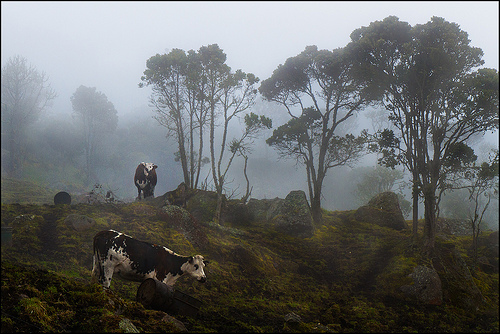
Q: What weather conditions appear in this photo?
A: It is foggy.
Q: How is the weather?
A: It is foggy.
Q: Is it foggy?
A: Yes, it is foggy.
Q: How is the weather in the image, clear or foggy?
A: It is foggy.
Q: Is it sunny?
A: No, it is foggy.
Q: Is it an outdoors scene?
A: Yes, it is outdoors.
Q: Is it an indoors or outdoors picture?
A: It is outdoors.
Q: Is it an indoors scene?
A: No, it is outdoors.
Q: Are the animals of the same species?
A: Yes, all the animals are cows.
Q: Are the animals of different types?
A: No, all the animals are cows.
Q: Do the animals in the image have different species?
A: No, all the animals are cows.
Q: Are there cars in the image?
A: No, there are no cars.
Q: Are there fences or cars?
A: No, there are no cars or fences.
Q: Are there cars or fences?
A: No, there are no cars or fences.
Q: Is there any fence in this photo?
A: No, there are no fences.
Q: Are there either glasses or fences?
A: No, there are no fences or glasses.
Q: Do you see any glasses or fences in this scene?
A: No, there are no fences or glasses.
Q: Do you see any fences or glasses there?
A: No, there are no fences or glasses.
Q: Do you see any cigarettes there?
A: No, there are no cigarettes.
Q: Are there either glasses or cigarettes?
A: No, there are no cigarettes or glasses.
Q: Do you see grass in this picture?
A: Yes, there is grass.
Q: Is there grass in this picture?
A: Yes, there is grass.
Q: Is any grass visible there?
A: Yes, there is grass.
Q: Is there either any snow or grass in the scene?
A: Yes, there is grass.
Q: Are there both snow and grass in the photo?
A: No, there is grass but no snow.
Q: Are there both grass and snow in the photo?
A: No, there is grass but no snow.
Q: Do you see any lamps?
A: No, there are no lamps.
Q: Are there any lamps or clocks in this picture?
A: No, there are no lamps or clocks.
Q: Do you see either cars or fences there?
A: No, there are no fences or cars.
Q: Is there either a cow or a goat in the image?
A: Yes, there is a cow.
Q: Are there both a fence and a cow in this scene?
A: No, there is a cow but no fences.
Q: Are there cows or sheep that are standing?
A: Yes, the cow is standing.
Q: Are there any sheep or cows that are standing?
A: Yes, the cow is standing.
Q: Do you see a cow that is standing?
A: Yes, there is a cow that is standing.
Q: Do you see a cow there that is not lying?
A: Yes, there is a cow that is standing .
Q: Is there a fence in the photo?
A: No, there are no fences.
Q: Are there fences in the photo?
A: No, there are no fences.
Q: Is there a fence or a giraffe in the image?
A: No, there are no fences or giraffes.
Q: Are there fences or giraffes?
A: No, there are no fences or giraffes.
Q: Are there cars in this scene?
A: No, there are no cars.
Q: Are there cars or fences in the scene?
A: No, there are no cars or fences.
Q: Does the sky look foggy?
A: Yes, the sky is foggy.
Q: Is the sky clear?
A: No, the sky is foggy.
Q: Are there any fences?
A: No, there are no fences.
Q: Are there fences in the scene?
A: No, there are no fences.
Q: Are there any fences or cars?
A: No, there are no fences or cars.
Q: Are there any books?
A: No, there are no books.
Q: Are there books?
A: No, there are no books.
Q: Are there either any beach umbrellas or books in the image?
A: No, there are no books or beach umbrellas.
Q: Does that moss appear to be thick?
A: Yes, the moss is thick.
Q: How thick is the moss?
A: The moss is thick.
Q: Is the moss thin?
A: No, the moss is thick.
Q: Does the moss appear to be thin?
A: No, the moss is thick.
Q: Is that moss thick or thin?
A: The moss is thick.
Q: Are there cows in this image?
A: Yes, there is a cow.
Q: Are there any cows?
A: Yes, there is a cow.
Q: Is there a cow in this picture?
A: Yes, there is a cow.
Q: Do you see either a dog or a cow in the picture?
A: Yes, there is a cow.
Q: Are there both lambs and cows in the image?
A: No, there is a cow but no lambs.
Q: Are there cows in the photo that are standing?
A: Yes, there is a cow that is standing.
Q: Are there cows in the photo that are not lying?
A: Yes, there is a cow that is standing.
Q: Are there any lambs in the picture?
A: No, there are no lambs.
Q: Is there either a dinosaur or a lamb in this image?
A: No, there are no lambs or dinosaurs.